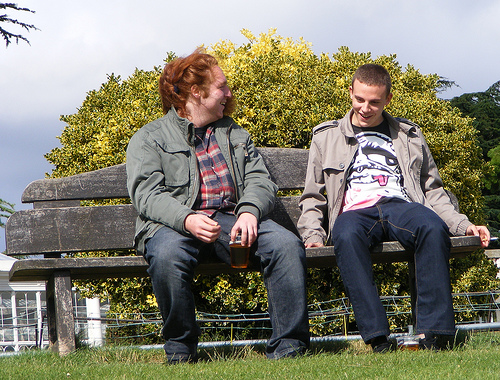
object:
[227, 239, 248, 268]
glass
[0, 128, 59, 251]
blue sky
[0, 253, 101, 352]
building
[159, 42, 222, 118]
hair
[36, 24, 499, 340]
tree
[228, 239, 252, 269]
drink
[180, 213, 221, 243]
hand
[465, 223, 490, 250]
hand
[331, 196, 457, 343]
jeans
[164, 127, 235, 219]
shirt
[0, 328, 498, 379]
grass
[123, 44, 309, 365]
person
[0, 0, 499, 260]
sky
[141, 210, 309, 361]
pants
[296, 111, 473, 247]
jacket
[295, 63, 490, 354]
man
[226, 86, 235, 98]
nose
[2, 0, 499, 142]
clouds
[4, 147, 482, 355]
wooden bench